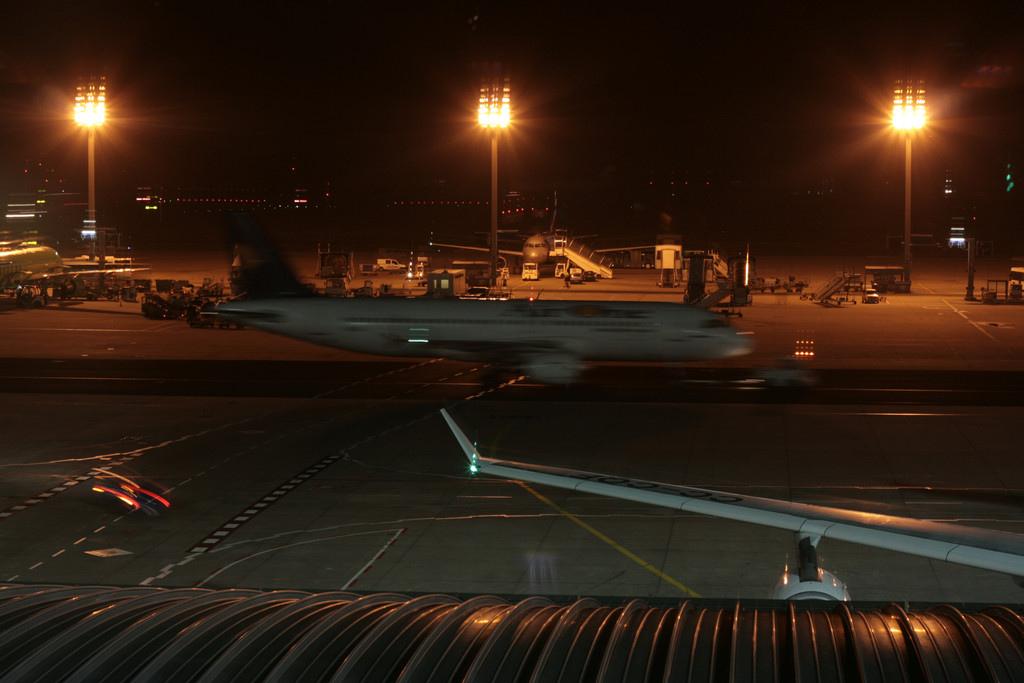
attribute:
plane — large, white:
[183, 257, 762, 418]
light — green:
[991, 162, 1022, 208]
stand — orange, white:
[52, 463, 232, 563]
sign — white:
[935, 223, 983, 256]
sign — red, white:
[127, 186, 169, 225]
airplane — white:
[183, 247, 789, 423]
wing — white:
[432, 432, 955, 627]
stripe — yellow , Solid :
[499, 445, 713, 593]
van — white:
[355, 251, 418, 280]